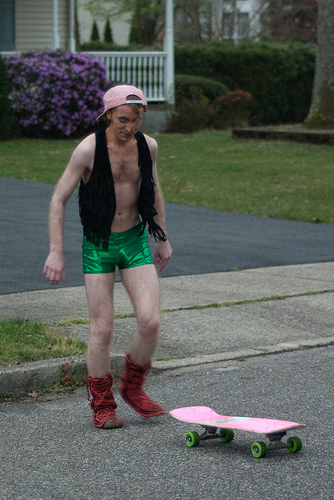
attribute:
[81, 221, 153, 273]
shorts — green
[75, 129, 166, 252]
vest — black, frilly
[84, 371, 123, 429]
boot — red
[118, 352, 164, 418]
boot — red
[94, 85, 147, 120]
hat — pink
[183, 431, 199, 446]
wheel — green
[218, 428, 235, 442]
wheel — green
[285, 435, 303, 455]
wheel — green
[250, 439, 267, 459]
wheel — green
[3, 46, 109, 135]
flower bush — purple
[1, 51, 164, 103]
porch — white